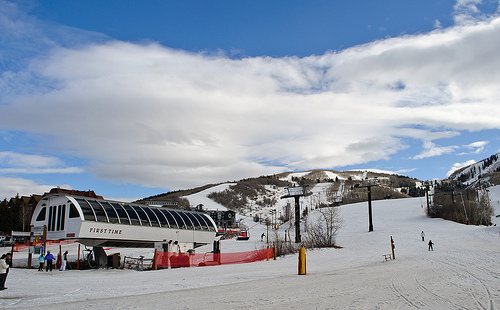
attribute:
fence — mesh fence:
[151, 252, 289, 263]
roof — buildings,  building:
[68, 194, 229, 245]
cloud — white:
[95, 55, 229, 177]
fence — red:
[153, 243, 269, 265]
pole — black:
[151, 251, 161, 279]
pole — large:
[363, 184, 380, 236]